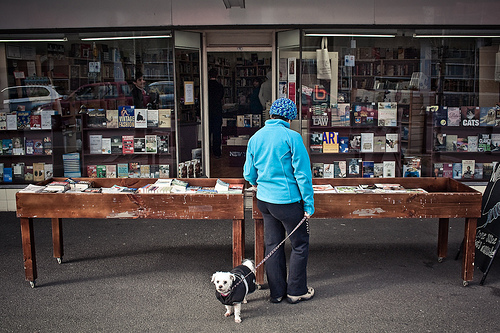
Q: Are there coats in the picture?
A: Yes, there is a coat.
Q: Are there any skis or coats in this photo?
A: Yes, there is a coat.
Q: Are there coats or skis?
A: Yes, there is a coat.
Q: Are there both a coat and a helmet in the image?
A: No, there is a coat but no helmets.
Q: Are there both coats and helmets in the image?
A: No, there is a coat but no helmets.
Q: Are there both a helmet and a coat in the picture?
A: No, there is a coat but no helmets.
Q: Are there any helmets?
A: No, there are no helmets.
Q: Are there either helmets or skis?
A: No, there are no helmets or skis.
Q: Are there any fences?
A: No, there are no fences.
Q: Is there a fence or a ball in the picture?
A: No, there are no fences or balls.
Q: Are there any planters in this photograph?
A: No, there are no planters.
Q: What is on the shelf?
A: The books are on the shelf.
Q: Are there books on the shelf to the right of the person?
A: Yes, there are books on the shelf.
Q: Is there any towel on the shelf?
A: No, there are books on the shelf.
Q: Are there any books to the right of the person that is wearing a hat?
A: Yes, there are books to the right of the person.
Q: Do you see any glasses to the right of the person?
A: No, there are books to the right of the person.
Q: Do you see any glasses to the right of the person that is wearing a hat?
A: No, there are books to the right of the person.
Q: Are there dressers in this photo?
A: No, there are no dressers.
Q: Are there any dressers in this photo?
A: No, there are no dressers.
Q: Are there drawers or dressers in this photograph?
A: No, there are no dressers or drawers.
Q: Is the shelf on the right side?
A: Yes, the shelf is on the right of the image.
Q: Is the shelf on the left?
A: No, the shelf is on the right of the image.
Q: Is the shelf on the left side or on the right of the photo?
A: The shelf is on the right of the image.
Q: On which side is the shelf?
A: The shelf is on the right of the image.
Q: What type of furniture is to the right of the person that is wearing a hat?
A: The piece of furniture is a shelf.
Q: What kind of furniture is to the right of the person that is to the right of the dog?
A: The piece of furniture is a shelf.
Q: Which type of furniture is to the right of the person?
A: The piece of furniture is a shelf.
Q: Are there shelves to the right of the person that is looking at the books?
A: Yes, there is a shelf to the right of the person.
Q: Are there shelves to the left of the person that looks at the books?
A: No, the shelf is to the right of the person.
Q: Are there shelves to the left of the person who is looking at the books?
A: No, the shelf is to the right of the person.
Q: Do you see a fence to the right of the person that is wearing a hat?
A: No, there is a shelf to the right of the person.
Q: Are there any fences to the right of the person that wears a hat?
A: No, there is a shelf to the right of the person.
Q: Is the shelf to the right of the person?
A: Yes, the shelf is to the right of the person.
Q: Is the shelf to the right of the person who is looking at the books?
A: Yes, the shelf is to the right of the person.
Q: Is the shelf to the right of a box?
A: No, the shelf is to the right of the person.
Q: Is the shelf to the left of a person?
A: No, the shelf is to the right of a person.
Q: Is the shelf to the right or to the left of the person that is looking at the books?
A: The shelf is to the right of the person.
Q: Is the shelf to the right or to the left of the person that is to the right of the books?
A: The shelf is to the right of the person.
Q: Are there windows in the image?
A: Yes, there is a window.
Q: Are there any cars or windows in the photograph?
A: Yes, there is a window.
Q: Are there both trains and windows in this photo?
A: No, there is a window but no trains.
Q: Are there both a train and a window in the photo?
A: No, there is a window but no trains.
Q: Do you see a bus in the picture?
A: No, there are no buses.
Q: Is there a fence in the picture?
A: No, there are no fences.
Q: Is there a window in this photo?
A: Yes, there is a window.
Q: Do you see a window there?
A: Yes, there is a window.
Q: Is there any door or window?
A: Yes, there is a window.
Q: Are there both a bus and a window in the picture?
A: No, there is a window but no buses.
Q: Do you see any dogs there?
A: Yes, there is a dog.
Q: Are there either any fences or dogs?
A: Yes, there is a dog.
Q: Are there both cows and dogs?
A: No, there is a dog but no cows.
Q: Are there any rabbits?
A: No, there are no rabbits.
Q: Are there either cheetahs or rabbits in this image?
A: No, there are no rabbits or cheetahs.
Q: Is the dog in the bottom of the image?
A: Yes, the dog is in the bottom of the image.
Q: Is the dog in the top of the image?
A: No, the dog is in the bottom of the image.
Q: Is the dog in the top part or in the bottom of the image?
A: The dog is in the bottom of the image.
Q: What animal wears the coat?
A: The dog wears a coat.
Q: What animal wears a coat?
A: The animal is a dog.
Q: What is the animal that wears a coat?
A: The animal is a dog.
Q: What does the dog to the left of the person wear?
A: The dog wears a coat.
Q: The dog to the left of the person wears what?
A: The dog wears a coat.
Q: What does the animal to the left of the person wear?
A: The dog wears a coat.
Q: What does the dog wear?
A: The dog wears a coat.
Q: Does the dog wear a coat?
A: Yes, the dog wears a coat.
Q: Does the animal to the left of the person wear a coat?
A: Yes, the dog wears a coat.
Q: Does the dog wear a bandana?
A: No, the dog wears a coat.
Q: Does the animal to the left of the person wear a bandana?
A: No, the dog wears a coat.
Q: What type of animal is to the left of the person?
A: The animal is a dog.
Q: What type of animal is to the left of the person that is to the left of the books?
A: The animal is a dog.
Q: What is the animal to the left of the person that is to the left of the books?
A: The animal is a dog.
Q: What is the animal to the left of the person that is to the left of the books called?
A: The animal is a dog.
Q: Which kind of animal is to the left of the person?
A: The animal is a dog.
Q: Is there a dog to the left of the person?
A: Yes, there is a dog to the left of the person.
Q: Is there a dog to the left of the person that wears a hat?
A: Yes, there is a dog to the left of the person.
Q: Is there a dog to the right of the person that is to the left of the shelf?
A: No, the dog is to the left of the person.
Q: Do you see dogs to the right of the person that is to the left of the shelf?
A: No, the dog is to the left of the person.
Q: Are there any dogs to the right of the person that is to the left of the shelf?
A: No, the dog is to the left of the person.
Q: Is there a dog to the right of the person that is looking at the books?
A: No, the dog is to the left of the person.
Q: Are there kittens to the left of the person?
A: No, there is a dog to the left of the person.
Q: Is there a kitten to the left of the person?
A: No, there is a dog to the left of the person.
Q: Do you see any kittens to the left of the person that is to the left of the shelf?
A: No, there is a dog to the left of the person.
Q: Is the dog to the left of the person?
A: Yes, the dog is to the left of the person.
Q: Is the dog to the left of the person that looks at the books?
A: Yes, the dog is to the left of the person.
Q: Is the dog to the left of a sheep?
A: No, the dog is to the left of the person.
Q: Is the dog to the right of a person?
A: No, the dog is to the left of a person.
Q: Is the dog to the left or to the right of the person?
A: The dog is to the left of the person.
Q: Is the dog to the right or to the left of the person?
A: The dog is to the left of the person.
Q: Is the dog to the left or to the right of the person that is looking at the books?
A: The dog is to the left of the person.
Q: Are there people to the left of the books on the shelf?
A: Yes, there is a person to the left of the books.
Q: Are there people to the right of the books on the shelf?
A: No, the person is to the left of the books.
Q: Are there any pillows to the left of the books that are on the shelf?
A: No, there is a person to the left of the books.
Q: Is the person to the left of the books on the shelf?
A: Yes, the person is to the left of the books.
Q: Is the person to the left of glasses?
A: No, the person is to the left of the books.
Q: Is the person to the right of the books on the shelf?
A: No, the person is to the left of the books.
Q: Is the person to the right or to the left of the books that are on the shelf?
A: The person is to the left of the books.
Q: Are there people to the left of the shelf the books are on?
A: Yes, there is a person to the left of the shelf.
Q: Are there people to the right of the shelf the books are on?
A: No, the person is to the left of the shelf.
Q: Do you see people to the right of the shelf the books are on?
A: No, the person is to the left of the shelf.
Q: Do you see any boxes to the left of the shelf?
A: No, there is a person to the left of the shelf.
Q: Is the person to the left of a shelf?
A: Yes, the person is to the left of a shelf.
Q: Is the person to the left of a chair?
A: No, the person is to the left of a shelf.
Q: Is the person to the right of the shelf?
A: No, the person is to the left of the shelf.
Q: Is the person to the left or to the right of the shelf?
A: The person is to the left of the shelf.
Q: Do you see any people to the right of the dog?
A: Yes, there is a person to the right of the dog.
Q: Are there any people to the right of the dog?
A: Yes, there is a person to the right of the dog.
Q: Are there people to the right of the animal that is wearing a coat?
A: Yes, there is a person to the right of the dog.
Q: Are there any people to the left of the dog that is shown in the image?
A: No, the person is to the right of the dog.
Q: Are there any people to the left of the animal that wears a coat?
A: No, the person is to the right of the dog.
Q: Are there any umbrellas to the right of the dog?
A: No, there is a person to the right of the dog.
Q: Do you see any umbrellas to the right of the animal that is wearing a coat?
A: No, there is a person to the right of the dog.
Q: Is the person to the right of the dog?
A: Yes, the person is to the right of the dog.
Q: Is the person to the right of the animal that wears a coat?
A: Yes, the person is to the right of the dog.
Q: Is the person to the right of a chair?
A: No, the person is to the right of the dog.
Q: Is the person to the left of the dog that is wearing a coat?
A: No, the person is to the right of the dog.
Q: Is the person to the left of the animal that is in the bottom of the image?
A: No, the person is to the right of the dog.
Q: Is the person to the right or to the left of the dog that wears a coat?
A: The person is to the right of the dog.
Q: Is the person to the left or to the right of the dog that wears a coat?
A: The person is to the right of the dog.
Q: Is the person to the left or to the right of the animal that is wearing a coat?
A: The person is to the right of the dog.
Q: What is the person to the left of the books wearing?
A: The person is wearing a hat.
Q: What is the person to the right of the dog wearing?
A: The person is wearing a hat.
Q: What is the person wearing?
A: The person is wearing a hat.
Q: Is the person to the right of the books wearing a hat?
A: Yes, the person is wearing a hat.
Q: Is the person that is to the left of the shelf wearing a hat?
A: Yes, the person is wearing a hat.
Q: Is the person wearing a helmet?
A: No, the person is wearing a hat.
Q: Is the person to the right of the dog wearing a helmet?
A: No, the person is wearing a hat.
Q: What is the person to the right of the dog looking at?
A: The person is looking at the books.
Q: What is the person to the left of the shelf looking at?
A: The person is looking at the books.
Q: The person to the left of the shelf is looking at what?
A: The person is looking at the books.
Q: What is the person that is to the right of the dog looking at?
A: The person is looking at the books.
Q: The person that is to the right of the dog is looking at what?
A: The person is looking at the books.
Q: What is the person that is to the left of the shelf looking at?
A: The person is looking at the books.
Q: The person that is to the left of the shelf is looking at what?
A: The person is looking at the books.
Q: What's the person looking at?
A: The person is looking at the books.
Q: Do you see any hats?
A: Yes, there is a hat.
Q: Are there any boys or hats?
A: Yes, there is a hat.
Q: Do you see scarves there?
A: No, there are no scarves.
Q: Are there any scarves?
A: No, there are no scarves.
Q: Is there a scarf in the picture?
A: No, there are no scarves.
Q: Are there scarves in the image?
A: No, there are no scarves.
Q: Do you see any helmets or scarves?
A: No, there are no scarves or helmets.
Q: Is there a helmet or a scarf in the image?
A: No, there are no scarves or helmets.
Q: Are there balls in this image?
A: No, there are no balls.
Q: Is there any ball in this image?
A: No, there are no balls.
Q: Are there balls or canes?
A: No, there are no balls or canes.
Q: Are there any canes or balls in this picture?
A: No, there are no balls or canes.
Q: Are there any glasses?
A: No, there are no glasses.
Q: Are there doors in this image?
A: Yes, there is a door.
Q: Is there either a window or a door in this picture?
A: Yes, there is a door.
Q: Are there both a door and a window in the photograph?
A: Yes, there are both a door and a window.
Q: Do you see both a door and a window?
A: Yes, there are both a door and a window.